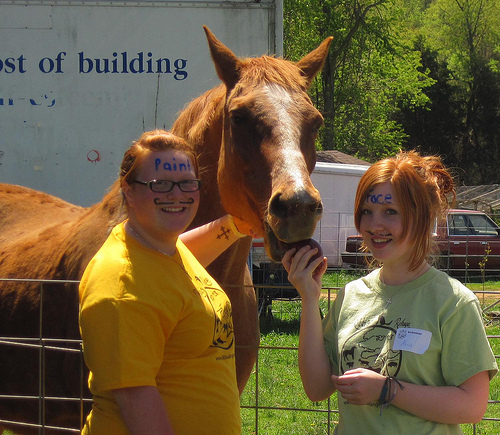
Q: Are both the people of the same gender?
A: Yes, all the people are female.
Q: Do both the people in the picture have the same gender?
A: Yes, all the people are female.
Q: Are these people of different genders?
A: No, all the people are female.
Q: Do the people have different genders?
A: No, all the people are female.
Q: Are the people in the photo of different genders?
A: No, all the people are female.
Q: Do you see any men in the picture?
A: No, there are no men.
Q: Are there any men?
A: No, there are no men.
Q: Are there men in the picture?
A: No, there are no men.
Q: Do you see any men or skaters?
A: No, there are no men or skaters.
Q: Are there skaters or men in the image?
A: No, there are no men or skaters.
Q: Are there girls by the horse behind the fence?
A: Yes, there is a girl by the horse.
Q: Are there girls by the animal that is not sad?
A: Yes, there is a girl by the horse.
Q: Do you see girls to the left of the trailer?
A: Yes, there is a girl to the left of the trailer.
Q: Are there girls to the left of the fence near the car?
A: Yes, there is a girl to the left of the fence.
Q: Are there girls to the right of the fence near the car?
A: No, the girl is to the left of the fence.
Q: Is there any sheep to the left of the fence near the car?
A: No, there is a girl to the left of the fence.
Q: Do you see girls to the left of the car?
A: Yes, there is a girl to the left of the car.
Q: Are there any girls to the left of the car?
A: Yes, there is a girl to the left of the car.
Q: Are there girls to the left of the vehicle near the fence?
A: Yes, there is a girl to the left of the car.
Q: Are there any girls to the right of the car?
A: No, the girl is to the left of the car.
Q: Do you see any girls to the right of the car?
A: No, the girl is to the left of the car.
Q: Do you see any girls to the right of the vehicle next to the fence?
A: No, the girl is to the left of the car.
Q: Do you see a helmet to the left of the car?
A: No, there is a girl to the left of the car.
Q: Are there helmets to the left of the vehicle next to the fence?
A: No, there is a girl to the left of the car.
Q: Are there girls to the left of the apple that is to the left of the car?
A: Yes, there is a girl to the left of the apple.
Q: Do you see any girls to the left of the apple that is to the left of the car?
A: Yes, there is a girl to the left of the apple.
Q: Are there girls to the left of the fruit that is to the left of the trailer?
A: Yes, there is a girl to the left of the apple.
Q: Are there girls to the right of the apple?
A: No, the girl is to the left of the apple.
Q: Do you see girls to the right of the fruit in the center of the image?
A: No, the girl is to the left of the apple.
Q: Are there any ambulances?
A: No, there are no ambulances.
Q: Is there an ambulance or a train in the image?
A: No, there are no ambulances or trains.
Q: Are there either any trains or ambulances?
A: No, there are no ambulances or trains.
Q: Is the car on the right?
A: Yes, the car is on the right of the image.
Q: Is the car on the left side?
A: No, the car is on the right of the image.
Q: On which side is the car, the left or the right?
A: The car is on the right of the image.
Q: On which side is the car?
A: The car is on the right of the image.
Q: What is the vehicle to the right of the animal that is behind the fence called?
A: The vehicle is a car.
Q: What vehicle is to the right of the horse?
A: The vehicle is a car.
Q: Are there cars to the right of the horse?
A: Yes, there is a car to the right of the horse.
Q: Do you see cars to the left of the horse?
A: No, the car is to the right of the horse.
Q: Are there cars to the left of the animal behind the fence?
A: No, the car is to the right of the horse.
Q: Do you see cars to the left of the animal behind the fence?
A: No, the car is to the right of the horse.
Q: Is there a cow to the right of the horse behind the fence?
A: No, there is a car to the right of the horse.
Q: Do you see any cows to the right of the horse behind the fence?
A: No, there is a car to the right of the horse.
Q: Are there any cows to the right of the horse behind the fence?
A: No, there is a car to the right of the horse.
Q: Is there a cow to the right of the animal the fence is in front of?
A: No, there is a car to the right of the horse.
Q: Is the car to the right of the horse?
A: Yes, the car is to the right of the horse.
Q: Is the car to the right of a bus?
A: No, the car is to the right of the horse.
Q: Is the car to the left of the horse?
A: No, the car is to the right of the horse.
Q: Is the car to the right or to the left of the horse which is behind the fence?
A: The car is to the right of the horse.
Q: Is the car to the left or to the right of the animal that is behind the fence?
A: The car is to the right of the horse.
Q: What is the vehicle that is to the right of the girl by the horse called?
A: The vehicle is a car.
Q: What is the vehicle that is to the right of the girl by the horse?
A: The vehicle is a car.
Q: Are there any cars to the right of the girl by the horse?
A: Yes, there is a car to the right of the girl.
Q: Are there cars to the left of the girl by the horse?
A: No, the car is to the right of the girl.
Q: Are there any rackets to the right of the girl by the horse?
A: No, there is a car to the right of the girl.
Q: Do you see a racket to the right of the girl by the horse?
A: No, there is a car to the right of the girl.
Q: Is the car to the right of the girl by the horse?
A: Yes, the car is to the right of the girl.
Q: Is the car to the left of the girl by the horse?
A: No, the car is to the right of the girl.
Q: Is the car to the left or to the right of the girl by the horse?
A: The car is to the right of the girl.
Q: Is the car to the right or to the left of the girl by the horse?
A: The car is to the right of the girl.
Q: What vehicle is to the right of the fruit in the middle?
A: The vehicle is a car.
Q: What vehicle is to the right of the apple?
A: The vehicle is a car.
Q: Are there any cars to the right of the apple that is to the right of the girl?
A: Yes, there is a car to the right of the apple.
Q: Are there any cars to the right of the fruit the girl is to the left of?
A: Yes, there is a car to the right of the apple.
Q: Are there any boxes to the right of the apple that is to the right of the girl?
A: No, there is a car to the right of the apple.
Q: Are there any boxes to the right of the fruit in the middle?
A: No, there is a car to the right of the apple.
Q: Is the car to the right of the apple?
A: Yes, the car is to the right of the apple.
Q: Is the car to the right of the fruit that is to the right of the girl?
A: Yes, the car is to the right of the apple.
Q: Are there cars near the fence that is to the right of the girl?
A: Yes, there is a car near the fence.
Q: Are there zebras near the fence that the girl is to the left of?
A: No, there is a car near the fence.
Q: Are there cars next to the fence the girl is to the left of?
A: Yes, there is a car next to the fence.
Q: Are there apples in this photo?
A: Yes, there is an apple.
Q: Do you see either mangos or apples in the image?
A: Yes, there is an apple.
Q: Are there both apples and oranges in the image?
A: No, there is an apple but no oranges.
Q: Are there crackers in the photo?
A: No, there are no crackers.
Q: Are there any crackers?
A: No, there are no crackers.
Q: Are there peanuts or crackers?
A: No, there are no crackers or peanuts.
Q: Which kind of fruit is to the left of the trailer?
A: The fruit is an apple.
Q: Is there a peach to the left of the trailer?
A: No, there is an apple to the left of the trailer.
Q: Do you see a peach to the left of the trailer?
A: No, there is an apple to the left of the trailer.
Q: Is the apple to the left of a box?
A: No, the apple is to the left of the trailer.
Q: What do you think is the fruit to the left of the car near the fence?
A: The fruit is an apple.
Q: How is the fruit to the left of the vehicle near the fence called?
A: The fruit is an apple.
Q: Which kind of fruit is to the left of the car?
A: The fruit is an apple.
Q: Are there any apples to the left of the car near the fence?
A: Yes, there is an apple to the left of the car.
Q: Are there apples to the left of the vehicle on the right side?
A: Yes, there is an apple to the left of the car.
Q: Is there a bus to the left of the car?
A: No, there is an apple to the left of the car.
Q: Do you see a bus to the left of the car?
A: No, there is an apple to the left of the car.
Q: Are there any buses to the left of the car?
A: No, there is an apple to the left of the car.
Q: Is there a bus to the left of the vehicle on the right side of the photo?
A: No, there is an apple to the left of the car.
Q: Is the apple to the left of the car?
A: Yes, the apple is to the left of the car.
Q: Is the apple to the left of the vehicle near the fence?
A: Yes, the apple is to the left of the car.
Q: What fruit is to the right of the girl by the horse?
A: The fruit is an apple.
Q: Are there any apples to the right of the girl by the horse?
A: Yes, there is an apple to the right of the girl.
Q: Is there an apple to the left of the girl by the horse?
A: No, the apple is to the right of the girl.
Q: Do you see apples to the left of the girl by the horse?
A: No, the apple is to the right of the girl.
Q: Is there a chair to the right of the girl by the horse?
A: No, there is an apple to the right of the girl.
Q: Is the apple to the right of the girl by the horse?
A: Yes, the apple is to the right of the girl.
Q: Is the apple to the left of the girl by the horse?
A: No, the apple is to the right of the girl.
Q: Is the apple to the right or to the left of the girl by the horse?
A: The apple is to the right of the girl.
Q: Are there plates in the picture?
A: No, there are no plates.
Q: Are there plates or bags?
A: No, there are no plates or bags.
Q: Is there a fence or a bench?
A: Yes, there is a fence.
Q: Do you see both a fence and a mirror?
A: No, there is a fence but no mirrors.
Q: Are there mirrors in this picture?
A: No, there are no mirrors.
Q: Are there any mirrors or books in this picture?
A: No, there are no mirrors or books.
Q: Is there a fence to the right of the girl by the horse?
A: Yes, there is a fence to the right of the girl.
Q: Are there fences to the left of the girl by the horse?
A: No, the fence is to the right of the girl.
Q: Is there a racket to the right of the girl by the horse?
A: No, there is a fence to the right of the girl.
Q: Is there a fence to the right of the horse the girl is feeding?
A: Yes, there is a fence to the right of the horse.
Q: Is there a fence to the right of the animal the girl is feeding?
A: Yes, there is a fence to the right of the horse.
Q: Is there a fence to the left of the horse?
A: No, the fence is to the right of the horse.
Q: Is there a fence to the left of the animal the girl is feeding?
A: No, the fence is to the right of the horse.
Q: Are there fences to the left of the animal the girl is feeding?
A: No, the fence is to the right of the horse.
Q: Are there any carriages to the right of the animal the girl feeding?
A: No, there is a fence to the right of the horse.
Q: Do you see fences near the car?
A: Yes, there is a fence near the car.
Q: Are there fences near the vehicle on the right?
A: Yes, there is a fence near the car.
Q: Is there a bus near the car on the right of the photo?
A: No, there is a fence near the car.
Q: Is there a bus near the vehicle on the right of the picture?
A: No, there is a fence near the car.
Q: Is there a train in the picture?
A: No, there are no trains.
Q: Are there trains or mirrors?
A: No, there are no trains or mirrors.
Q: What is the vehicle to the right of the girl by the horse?
A: The vehicle is a trailer.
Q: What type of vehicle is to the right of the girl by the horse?
A: The vehicle is a trailer.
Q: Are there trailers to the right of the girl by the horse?
A: Yes, there is a trailer to the right of the girl.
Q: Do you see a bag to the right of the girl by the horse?
A: No, there is a trailer to the right of the girl.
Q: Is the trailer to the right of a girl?
A: Yes, the trailer is to the right of a girl.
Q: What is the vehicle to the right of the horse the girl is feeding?
A: The vehicle is a trailer.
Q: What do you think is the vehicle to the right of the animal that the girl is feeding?
A: The vehicle is a trailer.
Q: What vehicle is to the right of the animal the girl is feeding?
A: The vehicle is a trailer.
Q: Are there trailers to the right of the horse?
A: Yes, there is a trailer to the right of the horse.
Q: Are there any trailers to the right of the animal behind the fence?
A: Yes, there is a trailer to the right of the horse.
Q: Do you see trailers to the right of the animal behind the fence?
A: Yes, there is a trailer to the right of the horse.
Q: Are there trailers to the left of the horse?
A: No, the trailer is to the right of the horse.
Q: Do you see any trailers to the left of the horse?
A: No, the trailer is to the right of the horse.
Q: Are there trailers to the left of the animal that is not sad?
A: No, the trailer is to the right of the horse.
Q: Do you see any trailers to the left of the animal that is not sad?
A: No, the trailer is to the right of the horse.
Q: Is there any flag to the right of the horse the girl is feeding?
A: No, there is a trailer to the right of the horse.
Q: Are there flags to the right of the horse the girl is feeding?
A: No, there is a trailer to the right of the horse.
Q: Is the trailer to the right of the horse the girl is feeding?
A: Yes, the trailer is to the right of the horse.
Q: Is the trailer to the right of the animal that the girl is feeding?
A: Yes, the trailer is to the right of the horse.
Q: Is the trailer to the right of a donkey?
A: No, the trailer is to the right of the horse.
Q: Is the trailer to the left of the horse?
A: No, the trailer is to the right of the horse.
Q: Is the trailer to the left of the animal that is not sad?
A: No, the trailer is to the right of the horse.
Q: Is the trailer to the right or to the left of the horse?
A: The trailer is to the right of the horse.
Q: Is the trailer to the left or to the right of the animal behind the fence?
A: The trailer is to the right of the horse.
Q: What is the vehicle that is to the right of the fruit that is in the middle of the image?
A: The vehicle is a trailer.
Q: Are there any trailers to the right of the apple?
A: Yes, there is a trailer to the right of the apple.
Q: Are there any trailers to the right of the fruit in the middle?
A: Yes, there is a trailer to the right of the apple.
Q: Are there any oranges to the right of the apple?
A: No, there is a trailer to the right of the apple.